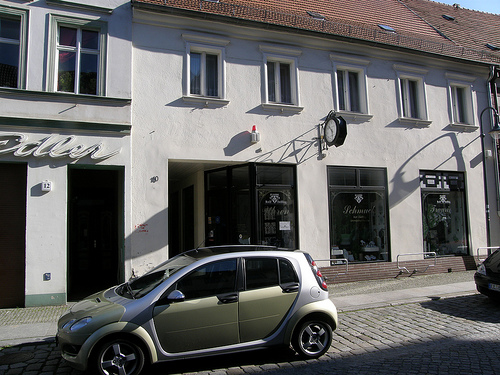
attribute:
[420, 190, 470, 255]
window — black glass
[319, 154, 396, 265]
window — large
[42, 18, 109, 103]
window — black glass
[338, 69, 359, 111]
window — black 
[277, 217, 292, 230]
sign — white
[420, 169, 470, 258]
window — large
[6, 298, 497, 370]
road —  cobblestone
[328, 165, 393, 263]
window — black glass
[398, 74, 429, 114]
window — black 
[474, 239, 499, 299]
car — parked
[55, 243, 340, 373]
car — small, parked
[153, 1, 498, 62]
roof — shingled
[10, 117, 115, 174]
sign — scripted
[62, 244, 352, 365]
car — green and silver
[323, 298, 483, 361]
street — cobblestone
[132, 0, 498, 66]
roof — brown, red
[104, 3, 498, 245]
building — gray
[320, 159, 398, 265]
windows — large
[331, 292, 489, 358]
street — brick